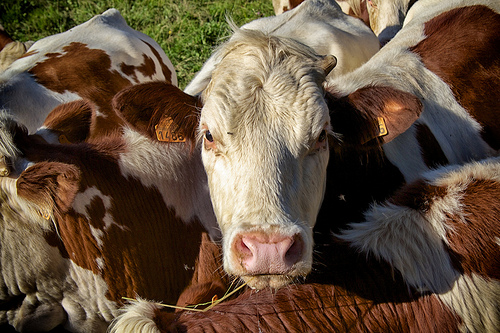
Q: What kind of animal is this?
A: Cow.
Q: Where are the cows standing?
A: Grass field.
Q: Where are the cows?
A: Green field.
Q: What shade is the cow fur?
A: Brown and white.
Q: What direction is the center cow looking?
A: Straight ahead.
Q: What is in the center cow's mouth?
A: Blades of grass.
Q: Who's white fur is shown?
A: The cow.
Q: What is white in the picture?
A: Cow fur.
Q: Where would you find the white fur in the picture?
A: The cow.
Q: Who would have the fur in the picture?
A: The white cow.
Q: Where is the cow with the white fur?
A: In the picture.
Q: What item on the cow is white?
A: Fur.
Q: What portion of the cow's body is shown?
A: Head.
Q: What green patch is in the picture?
A: Grass.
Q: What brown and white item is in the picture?
A: Cow.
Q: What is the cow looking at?
A: The camera.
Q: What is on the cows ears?
A: Tags.